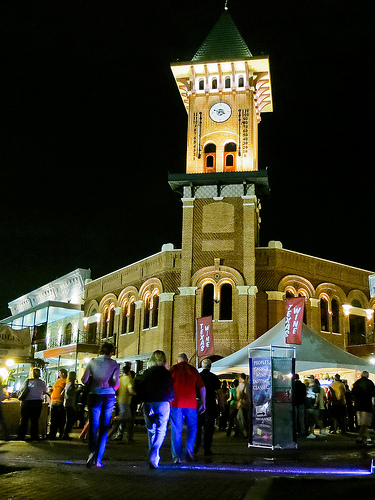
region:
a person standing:
[132, 345, 168, 470]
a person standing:
[169, 346, 207, 466]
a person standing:
[81, 335, 122, 471]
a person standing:
[18, 363, 48, 441]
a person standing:
[45, 362, 68, 437]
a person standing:
[196, 356, 231, 463]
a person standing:
[349, 369, 374, 442]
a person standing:
[330, 366, 349, 432]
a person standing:
[107, 355, 134, 444]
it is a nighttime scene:
[0, 0, 374, 497]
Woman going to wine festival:
[138, 350, 175, 470]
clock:
[206, 100, 232, 122]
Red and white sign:
[192, 314, 215, 357]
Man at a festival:
[327, 373, 349, 435]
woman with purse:
[17, 368, 47, 444]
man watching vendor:
[45, 367, 69, 440]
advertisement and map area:
[247, 345, 297, 451]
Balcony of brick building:
[46, 328, 101, 356]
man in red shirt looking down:
[161, 352, 206, 463]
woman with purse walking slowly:
[81, 342, 120, 469]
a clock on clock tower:
[207, 100, 232, 124]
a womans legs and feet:
[81, 410, 113, 468]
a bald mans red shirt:
[177, 370, 196, 403]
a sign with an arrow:
[254, 397, 267, 422]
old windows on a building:
[199, 279, 236, 321]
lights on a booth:
[1, 358, 18, 371]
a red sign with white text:
[284, 296, 303, 343]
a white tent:
[239, 319, 328, 367]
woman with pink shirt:
[26, 381, 44, 397]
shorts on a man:
[353, 406, 373, 449]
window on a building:
[194, 270, 234, 326]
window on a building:
[319, 290, 343, 335]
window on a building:
[137, 287, 163, 332]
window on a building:
[102, 300, 120, 340]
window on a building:
[201, 135, 216, 171]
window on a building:
[210, 76, 221, 93]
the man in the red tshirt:
[165, 350, 206, 465]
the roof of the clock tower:
[182, 3, 266, 65]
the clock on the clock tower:
[203, 101, 233, 122]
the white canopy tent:
[210, 308, 372, 380]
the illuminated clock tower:
[159, 2, 279, 194]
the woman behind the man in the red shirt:
[139, 346, 172, 466]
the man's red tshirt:
[165, 363, 204, 410]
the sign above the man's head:
[188, 312, 220, 362]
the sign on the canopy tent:
[286, 293, 314, 350]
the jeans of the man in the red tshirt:
[170, 405, 197, 459]